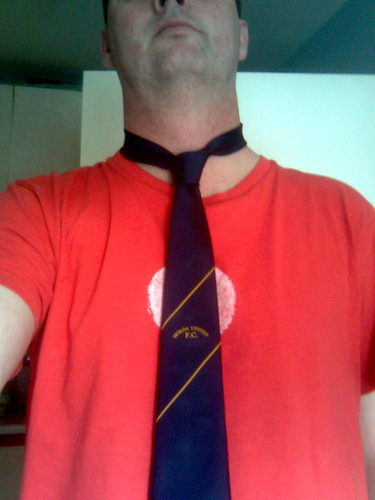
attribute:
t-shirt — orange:
[1, 149, 373, 498]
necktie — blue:
[124, 117, 250, 498]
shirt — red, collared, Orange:
[2, 156, 372, 498]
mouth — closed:
[140, 12, 228, 51]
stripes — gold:
[153, 250, 232, 439]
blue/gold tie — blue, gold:
[119, 122, 249, 497]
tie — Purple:
[114, 109, 257, 499]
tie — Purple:
[116, 121, 246, 498]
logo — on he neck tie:
[162, 323, 235, 357]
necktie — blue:
[165, 170, 240, 260]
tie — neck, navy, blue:
[147, 172, 217, 498]